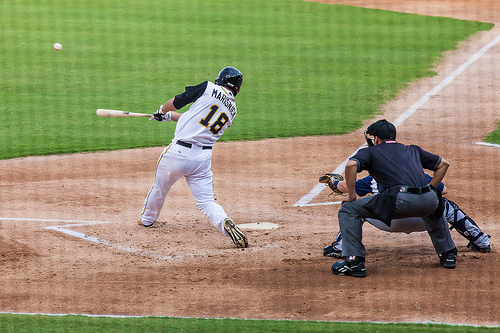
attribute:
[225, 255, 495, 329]
ground — brown, sandy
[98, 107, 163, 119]
club — pitch, wooden, wood, baseball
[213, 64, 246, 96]
helmet — black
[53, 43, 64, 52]
baseball — white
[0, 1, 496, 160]
ground — green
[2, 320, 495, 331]
grass — green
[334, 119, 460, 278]
umpire — squatting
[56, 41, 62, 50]
ball — heading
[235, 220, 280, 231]
plate — white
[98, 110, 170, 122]
bat — cricket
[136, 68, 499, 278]
players — these